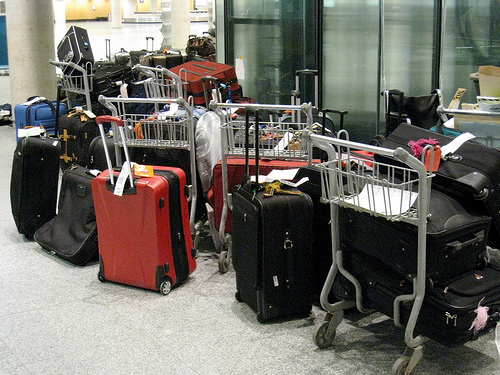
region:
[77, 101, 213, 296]
The suitcase is red.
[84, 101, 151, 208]
The suitcase's handle is up.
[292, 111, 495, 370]
Several suitcases are on the cart.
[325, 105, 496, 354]
The suitcases are black.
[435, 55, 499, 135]
Boxes are behind the suitcases.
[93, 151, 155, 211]
A tag is on the suitcase.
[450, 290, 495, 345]
A pink object is on the suitcase.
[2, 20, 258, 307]
Several suitcases are together.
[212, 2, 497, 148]
A wall is behind the suitcase.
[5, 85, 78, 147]
The suitcase is blue.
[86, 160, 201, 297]
Red rolling luggage bag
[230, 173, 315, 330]
Black rolling luggage bag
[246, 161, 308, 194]
White luggage tags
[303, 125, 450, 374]
Convenient luggage carrying carts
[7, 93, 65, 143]
Blue rolling luggage bag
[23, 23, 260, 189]
Luggage stacked on top of each other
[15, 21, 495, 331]
Luggage bags for travelers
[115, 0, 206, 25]
Airport baggage claim area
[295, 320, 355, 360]
Small rubber cart wheels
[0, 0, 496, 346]
Traveling luggage bags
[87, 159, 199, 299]
a red and black luggage case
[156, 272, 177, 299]
a black wheel on the luggage case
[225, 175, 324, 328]
a black luggage case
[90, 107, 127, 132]
a red handle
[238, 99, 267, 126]
a black handle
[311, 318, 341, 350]
a wheel on the cart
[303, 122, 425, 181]
a handle on the cart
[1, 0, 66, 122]
a large gray pillar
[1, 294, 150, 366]
a gray tile on the floor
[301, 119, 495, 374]
a gray cart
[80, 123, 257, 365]
the luggage is red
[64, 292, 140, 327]
small lines in gray floor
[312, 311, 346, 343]
gray wheels on luggage cart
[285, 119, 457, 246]
gray basket on luggage holder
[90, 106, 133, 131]
red handle on suitcase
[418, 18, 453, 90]
black frame on windows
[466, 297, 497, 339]
pink symbol on black luggage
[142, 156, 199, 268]
black stripe on red suitcase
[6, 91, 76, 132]
blue and black suit case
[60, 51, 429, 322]
selection of luggages on floor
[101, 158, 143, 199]
id tag on luggage